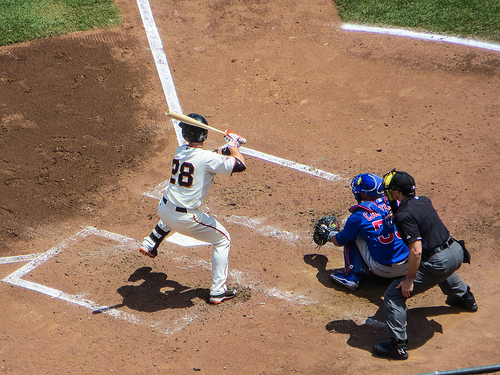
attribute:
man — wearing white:
[139, 111, 246, 322]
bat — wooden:
[159, 108, 246, 145]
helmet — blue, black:
[178, 114, 206, 139]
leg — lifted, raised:
[138, 217, 168, 262]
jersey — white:
[162, 146, 236, 198]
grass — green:
[5, 1, 123, 46]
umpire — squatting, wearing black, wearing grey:
[371, 168, 478, 359]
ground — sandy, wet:
[6, 18, 495, 369]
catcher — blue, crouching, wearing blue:
[319, 177, 416, 290]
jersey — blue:
[356, 197, 408, 267]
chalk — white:
[3, 220, 243, 342]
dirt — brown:
[1, 32, 140, 244]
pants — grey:
[382, 238, 471, 354]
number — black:
[167, 158, 194, 181]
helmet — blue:
[354, 176, 387, 192]